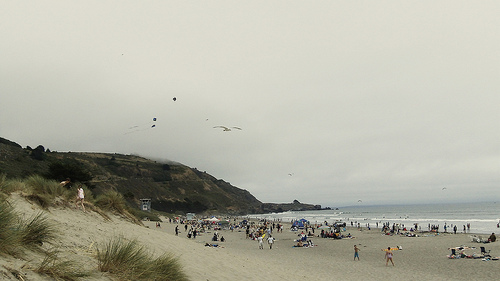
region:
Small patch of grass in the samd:
[93, 233, 188, 280]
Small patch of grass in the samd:
[20, 211, 53, 247]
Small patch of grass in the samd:
[36, 248, 81, 280]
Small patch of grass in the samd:
[25, 170, 57, 200]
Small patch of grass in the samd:
[94, 180, 131, 216]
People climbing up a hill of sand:
[55, 176, 93, 218]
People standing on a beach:
[163, 213, 200, 248]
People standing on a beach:
[194, 194, 231, 251]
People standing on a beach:
[221, 206, 263, 241]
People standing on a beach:
[253, 204, 310, 253]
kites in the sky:
[133, 85, 184, 139]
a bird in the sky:
[204, 115, 241, 137]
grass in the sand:
[13, 215, 148, 279]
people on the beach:
[171, 210, 498, 270]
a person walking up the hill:
[75, 181, 95, 220]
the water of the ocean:
[293, 198, 499, 239]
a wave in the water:
[321, 209, 493, 228]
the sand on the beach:
[266, 250, 484, 277]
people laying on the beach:
[444, 237, 496, 260]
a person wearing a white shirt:
[267, 233, 276, 246]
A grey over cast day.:
[291, 32, 471, 138]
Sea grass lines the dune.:
[17, 233, 195, 279]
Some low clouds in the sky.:
[345, 148, 489, 210]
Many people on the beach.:
[160, 210, 392, 262]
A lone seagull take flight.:
[205, 122, 255, 143]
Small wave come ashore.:
[369, 210, 492, 228]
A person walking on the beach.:
[373, 237, 408, 269]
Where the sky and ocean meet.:
[407, 184, 489, 219]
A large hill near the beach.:
[27, 152, 254, 216]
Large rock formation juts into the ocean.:
[255, 195, 329, 221]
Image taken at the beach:
[9, 7, 491, 269]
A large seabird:
[200, 109, 256, 141]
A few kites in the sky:
[97, 85, 192, 154]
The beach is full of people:
[154, 182, 496, 279]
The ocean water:
[345, 200, 498, 225]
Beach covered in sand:
[195, 244, 335, 279]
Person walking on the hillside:
[66, 173, 93, 218]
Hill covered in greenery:
[15, 145, 207, 210]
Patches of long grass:
[12, 212, 172, 279]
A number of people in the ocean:
[322, 201, 421, 226]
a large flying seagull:
[210, 120, 242, 138]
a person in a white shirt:
[65, 179, 93, 210]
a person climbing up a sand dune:
[67, 180, 89, 214]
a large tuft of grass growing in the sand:
[90, 232, 155, 279]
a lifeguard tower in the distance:
[137, 196, 154, 216]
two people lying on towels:
[442, 240, 494, 267]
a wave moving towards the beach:
[262, 204, 498, 229]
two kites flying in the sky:
[117, 111, 161, 138]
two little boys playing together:
[346, 237, 398, 266]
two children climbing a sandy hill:
[50, 170, 89, 217]